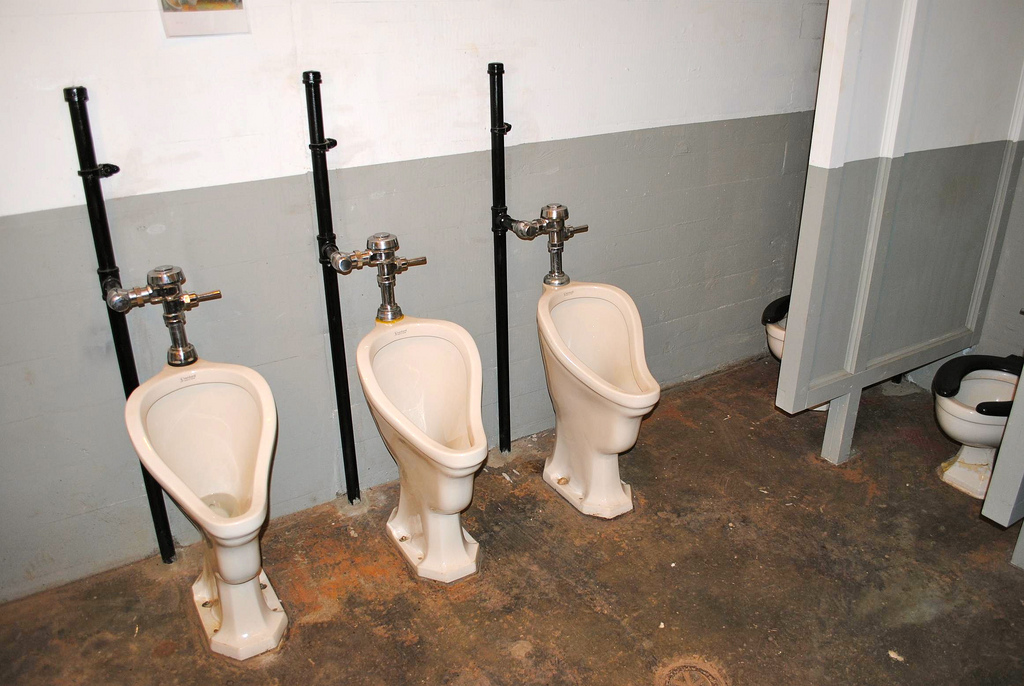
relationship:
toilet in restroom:
[919, 289, 1022, 504] [51, 63, 1022, 613]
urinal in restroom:
[458, 158, 690, 495] [51, 63, 1022, 613]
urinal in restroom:
[259, 149, 519, 523] [51, 63, 1022, 613]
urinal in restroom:
[123, 360, 288, 662] [51, 63, 1022, 613]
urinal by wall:
[82, 301, 307, 557] [14, 10, 1021, 566]